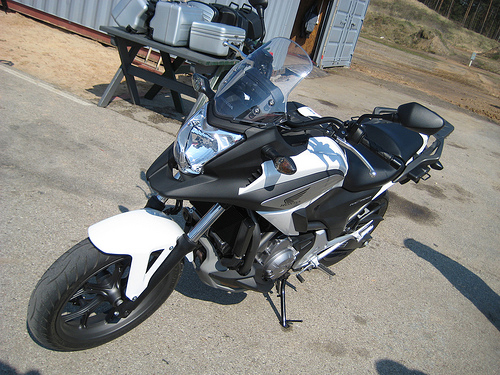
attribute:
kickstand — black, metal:
[278, 270, 293, 328]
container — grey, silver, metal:
[110, 0, 154, 38]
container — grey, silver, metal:
[148, 0, 201, 50]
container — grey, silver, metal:
[188, 20, 247, 59]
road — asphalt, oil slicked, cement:
[1, 63, 500, 373]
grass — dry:
[360, 1, 499, 74]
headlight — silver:
[174, 104, 243, 176]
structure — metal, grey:
[1, 1, 368, 70]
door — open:
[284, 0, 332, 66]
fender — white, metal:
[88, 208, 196, 301]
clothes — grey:
[299, 2, 319, 37]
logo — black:
[281, 185, 311, 208]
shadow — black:
[401, 236, 498, 333]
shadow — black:
[368, 353, 429, 373]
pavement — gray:
[6, 58, 497, 369]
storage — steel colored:
[0, 0, 368, 67]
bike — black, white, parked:
[25, 36, 455, 351]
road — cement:
[2, 66, 149, 208]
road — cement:
[166, 295, 496, 373]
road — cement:
[391, 183, 496, 290]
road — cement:
[301, 79, 403, 106]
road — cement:
[455, 108, 499, 155]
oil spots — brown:
[319, 325, 375, 359]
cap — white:
[86, 205, 186, 302]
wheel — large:
[25, 207, 184, 353]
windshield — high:
[213, 34, 313, 126]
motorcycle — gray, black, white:
[24, 36, 456, 354]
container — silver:
[312, 8, 367, 72]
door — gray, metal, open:
[318, 2, 370, 69]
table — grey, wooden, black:
[94, 23, 240, 110]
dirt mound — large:
[370, 11, 437, 56]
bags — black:
[218, 9, 265, 41]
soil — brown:
[0, 10, 123, 94]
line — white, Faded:
[0, 57, 91, 110]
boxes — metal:
[102, 0, 247, 59]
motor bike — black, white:
[21, 32, 456, 353]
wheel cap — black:
[99, 278, 126, 312]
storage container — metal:
[2, 6, 367, 72]